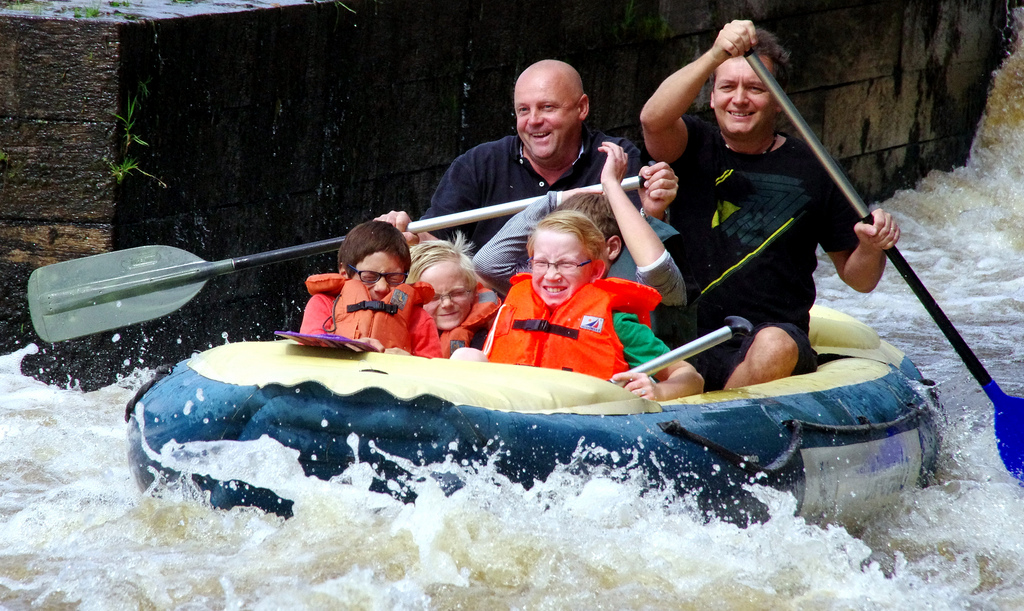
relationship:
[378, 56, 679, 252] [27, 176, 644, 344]
person holding paddle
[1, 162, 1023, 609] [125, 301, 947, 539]
water below raft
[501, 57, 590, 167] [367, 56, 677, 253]
part on person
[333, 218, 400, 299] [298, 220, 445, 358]
part on boy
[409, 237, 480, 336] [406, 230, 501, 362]
part on boy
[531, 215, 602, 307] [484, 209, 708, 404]
part on boy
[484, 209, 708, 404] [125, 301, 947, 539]
boy in raft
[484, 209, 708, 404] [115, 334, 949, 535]
boy in raft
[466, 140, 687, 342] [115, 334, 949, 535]
girl in raft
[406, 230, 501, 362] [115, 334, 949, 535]
boy in raft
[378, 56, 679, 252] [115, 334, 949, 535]
person sitting in raft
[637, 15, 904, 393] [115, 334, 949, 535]
person sitting in raft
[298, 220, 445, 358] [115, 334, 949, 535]
boy sitting in raft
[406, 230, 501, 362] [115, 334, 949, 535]
boy sitting in raft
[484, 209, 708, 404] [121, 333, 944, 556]
boy sitting in raft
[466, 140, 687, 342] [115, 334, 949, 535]
girl sitting in raft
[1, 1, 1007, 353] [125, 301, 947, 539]
wall behind raft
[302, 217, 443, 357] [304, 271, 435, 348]
boy wearing vest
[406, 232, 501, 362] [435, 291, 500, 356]
boy wearing vest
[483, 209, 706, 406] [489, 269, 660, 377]
boy wearing vest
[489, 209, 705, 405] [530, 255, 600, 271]
girl wearing glasses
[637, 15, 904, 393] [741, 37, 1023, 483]
person holding paddle